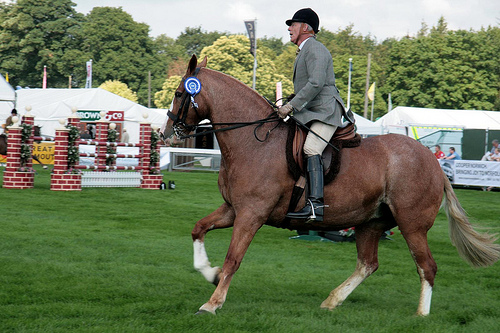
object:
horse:
[155, 55, 500, 317]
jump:
[70, 125, 158, 191]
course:
[0, 114, 165, 193]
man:
[269, 6, 353, 221]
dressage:
[157, 8, 499, 319]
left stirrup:
[285, 197, 325, 222]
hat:
[286, 7, 319, 33]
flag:
[366, 82, 377, 123]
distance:
[67, 14, 497, 109]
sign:
[454, 160, 499, 188]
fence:
[168, 146, 220, 172]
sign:
[75, 110, 125, 121]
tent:
[5, 87, 166, 144]